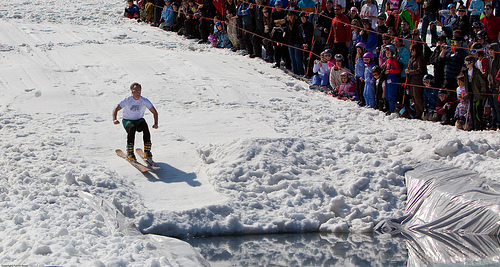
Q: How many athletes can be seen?
A: Just 1 skier.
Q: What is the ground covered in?
A: Snow.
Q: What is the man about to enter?
A: A water pit.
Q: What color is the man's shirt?
A: It is white.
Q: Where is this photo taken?
A: On a ski slope.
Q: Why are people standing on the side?
A: They are watching the race.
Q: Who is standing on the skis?
A: A man.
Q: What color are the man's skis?
A: Brown.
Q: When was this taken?
A: Daytime.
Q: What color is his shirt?
A: White.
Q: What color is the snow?
A: White.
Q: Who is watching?
A: Fans.